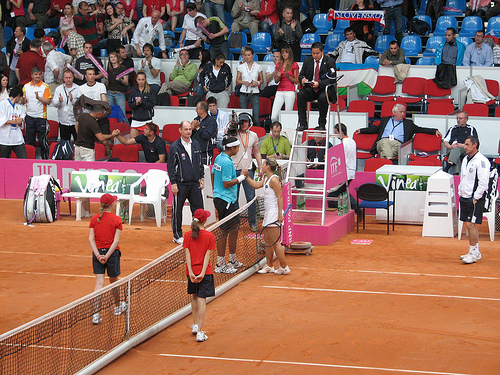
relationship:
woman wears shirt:
[142, 169, 220, 343] [182, 213, 218, 277]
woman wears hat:
[142, 169, 220, 343] [185, 210, 207, 225]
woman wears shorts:
[142, 169, 220, 343] [177, 269, 217, 298]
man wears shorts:
[450, 139, 488, 276] [451, 191, 480, 224]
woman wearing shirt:
[142, 169, 220, 343] [182, 213, 218, 277]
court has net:
[137, 256, 490, 370] [25, 256, 194, 374]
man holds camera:
[238, 112, 257, 232] [228, 111, 246, 142]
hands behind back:
[184, 273, 212, 276] [180, 228, 224, 263]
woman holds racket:
[257, 157, 292, 279] [259, 202, 284, 254]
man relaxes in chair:
[364, 104, 445, 170] [354, 127, 434, 160]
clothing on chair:
[421, 61, 498, 120] [458, 72, 498, 114]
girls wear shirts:
[65, 197, 221, 345] [90, 213, 216, 269]